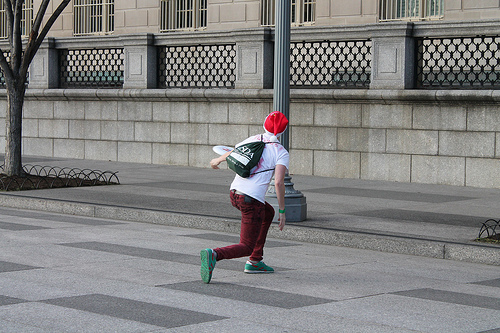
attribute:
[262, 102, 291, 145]
hat — santa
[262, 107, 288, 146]
hat — red, white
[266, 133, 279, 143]
ball — white, fuzzy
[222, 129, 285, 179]
backpack — black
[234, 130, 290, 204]
shirt — white, short sleeve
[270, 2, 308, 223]
pole — tall, grey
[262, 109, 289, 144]
hat — red, santa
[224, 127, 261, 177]
bag — black and white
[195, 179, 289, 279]
pants — maroon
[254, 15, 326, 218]
post — large grey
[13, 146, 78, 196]
dirt — brown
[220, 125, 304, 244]
shirt — white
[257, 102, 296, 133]
santa hat — red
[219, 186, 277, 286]
pants — dark red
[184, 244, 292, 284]
sneakers — bright green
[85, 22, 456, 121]
patterned fencing — black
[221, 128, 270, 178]
backpack — dark green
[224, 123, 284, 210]
t shirt — white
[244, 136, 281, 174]
lettering — red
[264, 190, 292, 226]
frisbee — white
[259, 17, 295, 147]
column — grayish green long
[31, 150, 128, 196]
wire fencing — semicircular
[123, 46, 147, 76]
detail — rectangular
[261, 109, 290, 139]
santa hat — red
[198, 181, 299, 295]
jeans — maroon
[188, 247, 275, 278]
shoes — green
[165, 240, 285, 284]
shoe — green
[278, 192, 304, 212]
wristband — green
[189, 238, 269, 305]
shoes — green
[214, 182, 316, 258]
pants — red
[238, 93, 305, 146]
hat — red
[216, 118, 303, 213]
shirt — white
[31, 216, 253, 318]
ground — stone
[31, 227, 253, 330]
sidewalk — grey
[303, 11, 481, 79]
guardrail — stone